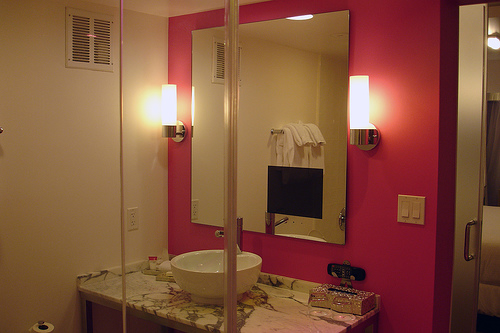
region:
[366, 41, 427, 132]
The wall is pink.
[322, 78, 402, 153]
The light is on.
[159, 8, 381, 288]
The mirror is large.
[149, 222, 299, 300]
The sink is a bowl.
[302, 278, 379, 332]
The kleenex is on the counter.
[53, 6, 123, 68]
The vent is on the wall.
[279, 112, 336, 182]
The towels are white.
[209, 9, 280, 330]
The mirror has a gold middle.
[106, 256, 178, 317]
The counter is granite.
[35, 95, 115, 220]
The wall is white.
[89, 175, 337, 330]
a bathroom sink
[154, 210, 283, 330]
a white bathroom sink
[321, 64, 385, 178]
a cylinder bathroom light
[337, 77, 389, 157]
a light on the wall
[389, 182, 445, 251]
a double light switch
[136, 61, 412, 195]
two lights on the wall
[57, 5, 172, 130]
a vent in the bathroom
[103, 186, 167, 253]
a light switch on the wall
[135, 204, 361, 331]
a bathroom sink on the counter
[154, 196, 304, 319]
a sink in the bathroom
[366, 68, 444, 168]
the wall is orange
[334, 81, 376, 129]
the lights are on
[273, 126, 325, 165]
the towels are white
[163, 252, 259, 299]
the plate is porcelain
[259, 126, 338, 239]
reflection is in the mirror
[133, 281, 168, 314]
the counter has graphics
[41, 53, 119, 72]
the vents are on the wall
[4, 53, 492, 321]
the room is a bathroom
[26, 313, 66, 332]
the toiler paper is halfly used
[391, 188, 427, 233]
the switch is a double switch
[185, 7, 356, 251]
a wall mounted mirror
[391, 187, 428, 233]
two wall light switches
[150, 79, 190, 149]
a wall mounted bathroom light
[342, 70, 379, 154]
a wall mounted bathroom light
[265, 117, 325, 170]
reflection of towels hanging on bar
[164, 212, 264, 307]
a bathroom sink basin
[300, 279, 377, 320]
a box of facial tissue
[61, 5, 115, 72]
a wall air vent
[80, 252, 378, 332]
a marble vanity top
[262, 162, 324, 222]
television inset screen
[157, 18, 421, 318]
red accent wall in photograph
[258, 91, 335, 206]
white towels on towel holder in mirror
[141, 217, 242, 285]
white round sink in photo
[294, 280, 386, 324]
empty tissue box on sink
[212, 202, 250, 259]
tall metal faucet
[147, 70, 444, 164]
two lights in bathroom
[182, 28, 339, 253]
large mirror over sink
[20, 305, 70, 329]
top of toilet paper roll visible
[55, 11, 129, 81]
air vent on white wall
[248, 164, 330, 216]
something black visible in mirror